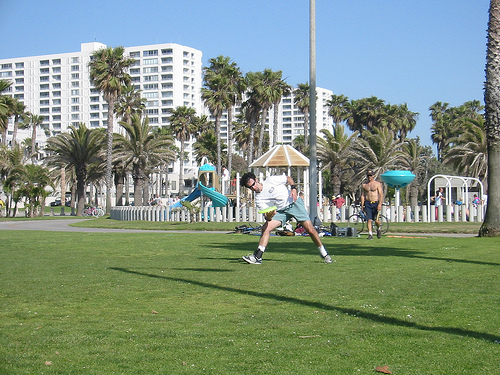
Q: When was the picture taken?
A: Daytime.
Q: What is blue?
A: Slide.